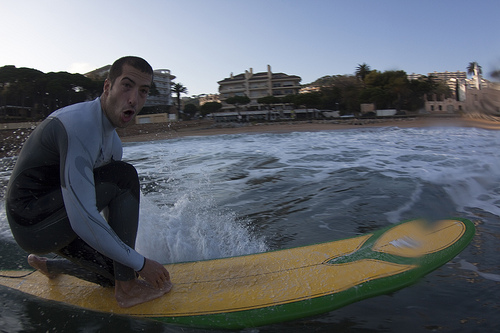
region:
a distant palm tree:
[354, 62, 373, 101]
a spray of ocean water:
[139, 160, 269, 255]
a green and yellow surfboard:
[7, 213, 477, 331]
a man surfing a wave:
[5, 51, 482, 330]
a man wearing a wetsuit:
[8, 54, 175, 307]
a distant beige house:
[216, 63, 306, 109]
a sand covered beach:
[185, 115, 470, 138]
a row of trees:
[3, 61, 100, 108]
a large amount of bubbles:
[361, 128, 471, 180]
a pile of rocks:
[138, 118, 213, 130]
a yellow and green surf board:
[0, 213, 485, 332]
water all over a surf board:
[0, 194, 470, 327]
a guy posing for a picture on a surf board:
[0, 45, 480, 315]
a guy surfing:
[2, 45, 472, 330]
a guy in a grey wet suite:
[4, 55, 176, 315]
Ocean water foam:
[1, 115, 498, 326]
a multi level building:
[214, 60, 309, 125]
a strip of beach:
[168, 113, 479, 134]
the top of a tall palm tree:
[351, 57, 373, 84]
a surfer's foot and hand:
[114, 253, 174, 312]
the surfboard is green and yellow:
[6, 203, 474, 318]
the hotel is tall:
[217, 62, 303, 127]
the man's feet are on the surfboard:
[21, 253, 173, 308]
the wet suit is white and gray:
[2, 93, 154, 285]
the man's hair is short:
[97, 51, 152, 127]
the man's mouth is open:
[100, 51, 151, 126]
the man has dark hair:
[98, 53, 149, 121]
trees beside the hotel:
[307, 60, 423, 120]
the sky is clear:
[0, 2, 497, 69]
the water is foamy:
[135, 119, 495, 214]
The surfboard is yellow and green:
[12, 198, 477, 315]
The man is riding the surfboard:
[8, 51, 183, 299]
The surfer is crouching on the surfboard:
[11, 51, 186, 303]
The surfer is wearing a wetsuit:
[6, 54, 186, 306]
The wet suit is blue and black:
[1, 49, 191, 303]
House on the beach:
[196, 64, 321, 125]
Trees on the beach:
[307, 69, 442, 114]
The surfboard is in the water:
[13, 206, 475, 316]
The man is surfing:
[4, 44, 477, 307]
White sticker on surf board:
[383, 231, 420, 254]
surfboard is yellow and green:
[234, 243, 396, 298]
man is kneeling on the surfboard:
[7, 208, 132, 327]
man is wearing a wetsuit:
[25, 122, 125, 222]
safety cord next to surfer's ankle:
[9, 248, 47, 291]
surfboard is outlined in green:
[281, 281, 330, 317]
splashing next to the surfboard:
[138, 199, 234, 252]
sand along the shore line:
[206, 123, 328, 136]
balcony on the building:
[247, 78, 280, 99]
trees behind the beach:
[329, 66, 403, 94]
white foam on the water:
[405, 128, 462, 164]